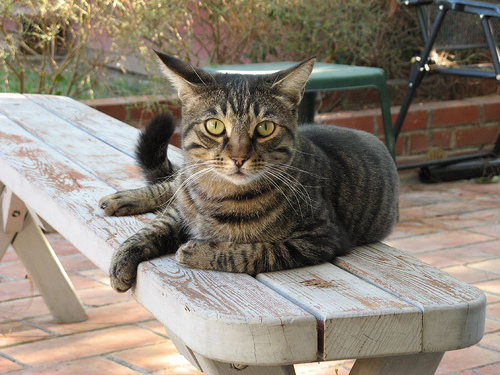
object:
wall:
[311, 96, 500, 172]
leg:
[111, 212, 189, 267]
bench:
[0, 82, 488, 375]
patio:
[0, 172, 499, 374]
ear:
[147, 47, 218, 94]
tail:
[130, 112, 184, 184]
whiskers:
[259, 169, 300, 217]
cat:
[97, 47, 403, 294]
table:
[190, 57, 400, 166]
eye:
[253, 119, 278, 138]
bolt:
[11, 208, 23, 219]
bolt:
[226, 358, 255, 375]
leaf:
[38, 6, 73, 35]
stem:
[0, 54, 31, 96]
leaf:
[209, 1, 247, 31]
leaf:
[72, 75, 101, 96]